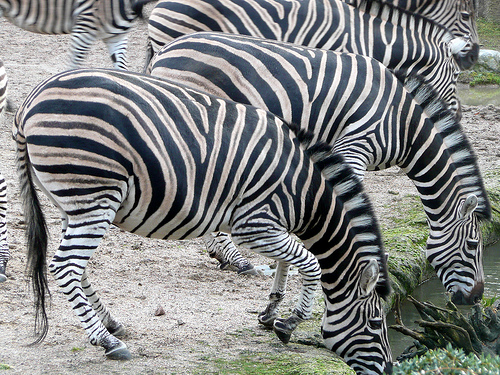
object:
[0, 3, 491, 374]
scene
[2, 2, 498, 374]
animals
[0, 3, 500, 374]
photo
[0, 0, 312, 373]
dirt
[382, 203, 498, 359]
spot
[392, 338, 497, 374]
patch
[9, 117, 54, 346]
tail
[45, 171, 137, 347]
leg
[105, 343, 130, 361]
hoof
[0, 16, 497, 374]
ground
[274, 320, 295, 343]
hoof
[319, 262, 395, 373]
head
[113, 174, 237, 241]
belly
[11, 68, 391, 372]
zebra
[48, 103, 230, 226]
stripe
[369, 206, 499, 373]
water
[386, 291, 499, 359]
roots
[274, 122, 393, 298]
mane